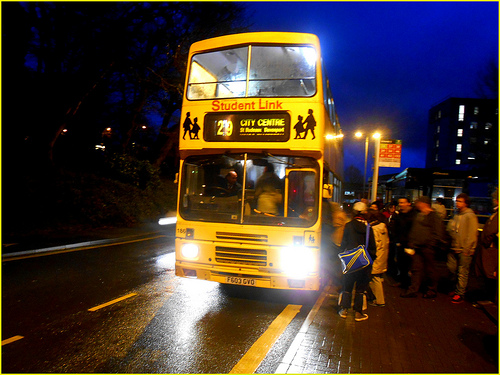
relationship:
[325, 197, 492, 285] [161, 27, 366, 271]
people waiting to get on bus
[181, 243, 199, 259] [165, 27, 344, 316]
headlight on bus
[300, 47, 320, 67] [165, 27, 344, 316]
light on bus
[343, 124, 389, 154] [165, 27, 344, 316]
lights on bus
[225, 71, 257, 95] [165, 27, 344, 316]
light on bus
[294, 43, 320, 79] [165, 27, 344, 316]
light inside bus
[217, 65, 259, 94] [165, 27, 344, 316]
light inside bus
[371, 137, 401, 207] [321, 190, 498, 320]
sign next to people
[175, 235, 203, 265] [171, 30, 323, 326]
headlight on bus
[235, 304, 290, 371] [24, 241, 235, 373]
yellow line on road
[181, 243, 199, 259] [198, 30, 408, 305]
headlight on bus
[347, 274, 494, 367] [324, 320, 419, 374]
sidewalk has brick sidewalk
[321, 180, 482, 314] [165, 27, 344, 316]
people boarding bus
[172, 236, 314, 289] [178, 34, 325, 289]
headlights on front bus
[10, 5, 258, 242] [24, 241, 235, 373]
trees on side road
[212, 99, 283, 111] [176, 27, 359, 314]
bus writing on bus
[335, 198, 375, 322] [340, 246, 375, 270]
person carrying bag